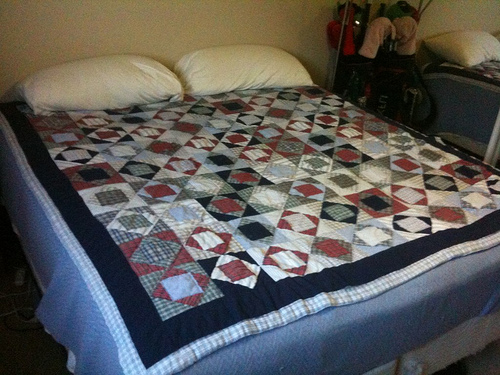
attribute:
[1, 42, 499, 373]
bed — queen size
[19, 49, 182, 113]
pillow — white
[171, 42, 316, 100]
pillow — white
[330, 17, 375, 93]
golf clubs — covered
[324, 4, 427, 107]
golf clubs — covered